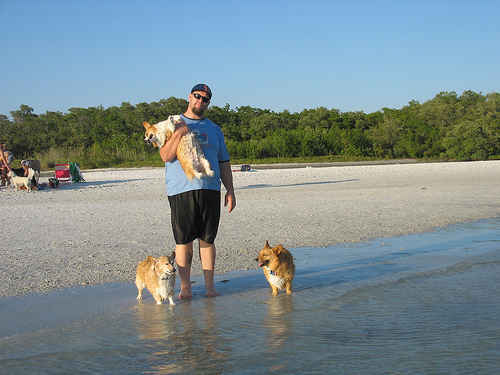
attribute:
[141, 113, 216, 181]
dog — stretched out, white, brown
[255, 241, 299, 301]
dog — colored brown, brown in color, white in color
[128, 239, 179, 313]
dog — white colored, white, brown colored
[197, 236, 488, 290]
shadow — skinny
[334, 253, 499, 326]
wave — small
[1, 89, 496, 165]
trees — thick, green colored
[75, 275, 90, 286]
pebble — a white color, brown in color, a brown color, brown color, white color, white in color, brown colored, brown, white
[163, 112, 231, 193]
shirt — blue colored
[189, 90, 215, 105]
sunglasses — dark